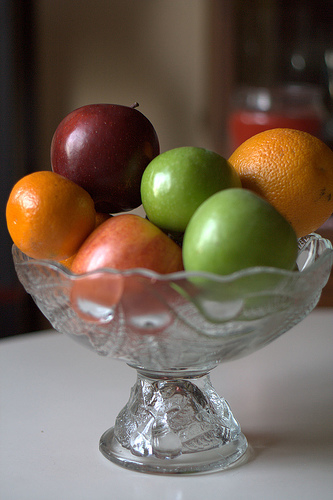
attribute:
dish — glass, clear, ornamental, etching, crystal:
[12, 207, 331, 476]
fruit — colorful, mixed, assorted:
[5, 103, 331, 310]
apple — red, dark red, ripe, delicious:
[50, 102, 159, 214]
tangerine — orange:
[5, 170, 95, 262]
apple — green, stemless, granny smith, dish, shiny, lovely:
[140, 144, 239, 233]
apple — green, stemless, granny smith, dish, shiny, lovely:
[179, 185, 299, 301]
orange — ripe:
[228, 127, 331, 238]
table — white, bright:
[0, 309, 332, 498]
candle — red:
[225, 82, 321, 157]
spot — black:
[312, 183, 332, 206]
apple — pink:
[68, 211, 198, 335]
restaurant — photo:
[0, 1, 330, 498]